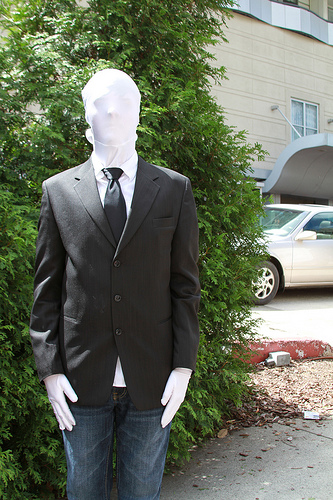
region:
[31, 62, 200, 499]
man wearing suit and full-body cover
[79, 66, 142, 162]
white full-face cover mask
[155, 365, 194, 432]
white glove on left hand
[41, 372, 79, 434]
white glove on right hand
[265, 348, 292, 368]
electric power box by driveway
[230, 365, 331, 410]
pile of wood chips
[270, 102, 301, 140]
pole holding up metal awning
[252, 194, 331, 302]
silver car parked in driveway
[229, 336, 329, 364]
parking curb with chipped red paint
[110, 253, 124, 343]
row of three buttons on suit coat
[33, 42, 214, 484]
a mannequin in suit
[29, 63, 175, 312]
a mannequin in suit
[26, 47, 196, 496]
mannequin wearing a coat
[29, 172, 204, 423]
the coat is black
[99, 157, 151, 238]
the tie is black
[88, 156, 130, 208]
the shirt is white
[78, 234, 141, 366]
the coat has buttons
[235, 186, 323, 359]
a car is parked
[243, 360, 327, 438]
dry leaves on the ground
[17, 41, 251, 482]
bush behind the manequin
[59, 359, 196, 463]
the jeans are blue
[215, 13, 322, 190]
the building made of concrete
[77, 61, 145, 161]
The face has been covered.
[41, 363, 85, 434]
The glove is white.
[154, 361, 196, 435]
The glove is covering a hand.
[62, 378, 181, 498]
The jeans are blue.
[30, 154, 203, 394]
A black suit jacket.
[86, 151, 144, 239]
A white dress shirt.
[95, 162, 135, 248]
The tie is black.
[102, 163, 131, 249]
The tie is shiny.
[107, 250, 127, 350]
Three round, black buttons.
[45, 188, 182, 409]
The jacket has buttons.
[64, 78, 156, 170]
a man with his face covered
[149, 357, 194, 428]
a man wearing white gloves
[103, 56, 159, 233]
a man wearing a black tie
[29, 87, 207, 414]
a man wearing a suit jacket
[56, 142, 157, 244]
a man wearing a white shirt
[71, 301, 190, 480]
a man wearing blue jeans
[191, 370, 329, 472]
brown leaves on the ground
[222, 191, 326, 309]
a car parked in driveway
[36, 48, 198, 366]
a man standing next to a tree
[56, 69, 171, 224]
a man wearing a white mask